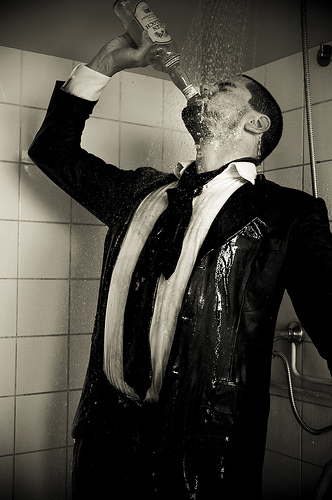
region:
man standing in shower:
[94, 8, 296, 288]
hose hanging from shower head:
[280, 40, 320, 160]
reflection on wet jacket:
[208, 213, 275, 304]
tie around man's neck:
[150, 155, 248, 249]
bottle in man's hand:
[119, 3, 191, 95]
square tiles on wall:
[9, 219, 78, 309]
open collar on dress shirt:
[218, 159, 262, 190]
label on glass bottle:
[133, 4, 171, 47]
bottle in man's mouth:
[168, 73, 210, 110]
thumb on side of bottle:
[132, 24, 155, 60]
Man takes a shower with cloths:
[23, 6, 330, 498]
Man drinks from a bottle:
[23, 3, 330, 498]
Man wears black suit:
[8, 37, 330, 498]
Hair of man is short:
[145, 55, 329, 184]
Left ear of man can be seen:
[239, 108, 271, 144]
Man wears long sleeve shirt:
[20, 22, 330, 433]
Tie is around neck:
[114, 147, 268, 401]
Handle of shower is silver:
[275, 320, 305, 384]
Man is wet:
[28, 35, 330, 498]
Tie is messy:
[97, 149, 252, 415]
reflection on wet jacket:
[198, 248, 258, 348]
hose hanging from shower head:
[292, 75, 321, 158]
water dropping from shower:
[188, 22, 245, 75]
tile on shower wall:
[8, 226, 77, 327]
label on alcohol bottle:
[132, 1, 177, 48]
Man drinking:
[16, 2, 330, 497]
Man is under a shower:
[23, 20, 330, 498]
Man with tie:
[18, 14, 330, 498]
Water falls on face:
[157, 15, 291, 206]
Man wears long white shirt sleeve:
[14, 7, 330, 418]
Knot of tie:
[153, 166, 213, 206]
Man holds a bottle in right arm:
[24, 3, 330, 289]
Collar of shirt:
[162, 151, 260, 185]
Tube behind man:
[272, 351, 330, 445]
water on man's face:
[189, 62, 237, 131]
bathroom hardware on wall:
[278, 324, 303, 354]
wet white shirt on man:
[152, 276, 188, 343]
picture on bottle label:
[151, 24, 170, 43]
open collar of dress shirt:
[223, 158, 264, 191]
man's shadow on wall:
[55, 222, 108, 302]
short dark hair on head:
[246, 71, 279, 116]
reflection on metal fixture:
[288, 321, 306, 344]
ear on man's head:
[243, 110, 275, 141]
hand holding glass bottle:
[110, 23, 161, 78]